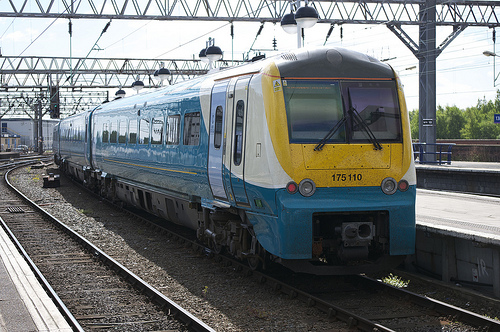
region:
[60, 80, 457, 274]
Train approaching the station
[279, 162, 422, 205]
head lights on a train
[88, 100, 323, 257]
green and white train car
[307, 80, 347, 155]
windshield wiper on a train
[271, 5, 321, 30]
lights over the train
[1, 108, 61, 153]
building behind the train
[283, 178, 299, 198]
yellow light on a train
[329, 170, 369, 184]
175110 number on the train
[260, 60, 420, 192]
yellow paint on the train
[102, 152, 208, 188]
yellow strip on a train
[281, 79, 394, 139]
the windshield of the train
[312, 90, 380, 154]
the black windshield wipers of the train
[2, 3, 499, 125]
the metal scaffolding above the train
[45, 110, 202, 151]
the windows on the side of the train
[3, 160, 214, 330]
the empty train tracks next to the bus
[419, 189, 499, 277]
the platform next to the train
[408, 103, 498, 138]
some green leafy trees off to the side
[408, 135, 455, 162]
a bench for people to sit on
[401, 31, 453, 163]
a metal pole to help hold up the scaffolding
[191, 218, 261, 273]
some wheels on the train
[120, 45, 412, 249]
this is a train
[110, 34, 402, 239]
the train is long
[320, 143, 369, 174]
the front is yellow in collor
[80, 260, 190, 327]
these are the rails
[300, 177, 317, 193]
the light is off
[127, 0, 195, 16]
this is a bridge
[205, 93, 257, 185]
this is the door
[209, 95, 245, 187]
the door is closed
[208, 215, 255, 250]
thee are the wheels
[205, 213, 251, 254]
the wheels are black in color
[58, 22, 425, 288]
Passenger train on the railway track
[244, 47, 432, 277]
electric locomotive cabin with wipers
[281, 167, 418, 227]
Two headlight with danger lamp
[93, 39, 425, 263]
Electric locomotive with passenger coach in it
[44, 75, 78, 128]
Railway signal appears green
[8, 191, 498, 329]
Railway track with stones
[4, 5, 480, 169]
Over head electric wire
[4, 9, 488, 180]
Giant iron post holding electric wire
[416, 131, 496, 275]
Railway platform in between the platforms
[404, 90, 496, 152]
Trees on the side of the railway platform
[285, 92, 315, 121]
part of a win dow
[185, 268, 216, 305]
part of a shade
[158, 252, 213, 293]
part of a ground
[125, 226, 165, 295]
part of a rail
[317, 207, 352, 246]
part of a train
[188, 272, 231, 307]
part of a ground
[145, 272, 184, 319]
edgfe of a rail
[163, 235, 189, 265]
part of a shade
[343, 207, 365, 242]
[part of a metal